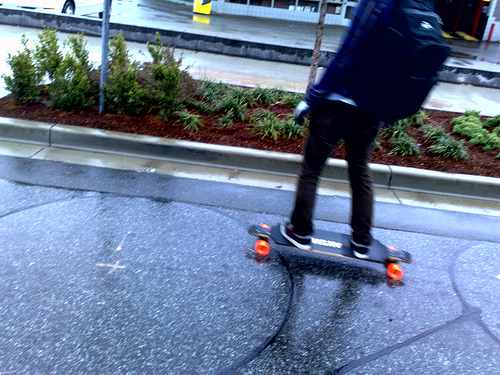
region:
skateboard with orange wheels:
[241, 214, 419, 284]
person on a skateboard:
[286, 0, 453, 272]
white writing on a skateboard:
[310, 234, 347, 252]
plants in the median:
[0, 25, 497, 165]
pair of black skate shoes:
[280, 218, 383, 260]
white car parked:
[1, 2, 121, 29]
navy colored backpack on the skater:
[349, 0, 456, 132]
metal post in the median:
[91, 1, 121, 114]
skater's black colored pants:
[288, 93, 378, 240]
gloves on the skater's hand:
[287, 97, 315, 127]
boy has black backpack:
[345, 3, 432, 134]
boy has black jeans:
[278, 89, 393, 289]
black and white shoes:
[254, 223, 392, 285]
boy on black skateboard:
[254, 223, 386, 290]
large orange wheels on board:
[388, 215, 408, 290]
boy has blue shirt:
[332, 9, 374, 123]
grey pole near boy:
[81, 8, 125, 136]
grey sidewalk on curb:
[11, 116, 293, 204]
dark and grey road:
[50, 196, 241, 370]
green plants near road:
[11, 32, 249, 137]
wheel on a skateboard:
[250, 237, 269, 259]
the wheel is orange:
[385, 263, 403, 283]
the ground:
[58, 274, 277, 357]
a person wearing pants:
[296, 135, 324, 225]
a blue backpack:
[389, 32, 432, 124]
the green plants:
[117, 70, 169, 108]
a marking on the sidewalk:
[88, 255, 138, 277]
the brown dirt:
[132, 111, 169, 136]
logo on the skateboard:
[315, 233, 342, 250]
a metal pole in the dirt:
[100, 38, 110, 115]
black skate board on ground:
[238, 214, 415, 280]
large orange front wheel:
[257, 239, 272, 260]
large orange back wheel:
[381, 257, 406, 283]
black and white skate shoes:
[352, 238, 366, 260]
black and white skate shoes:
[281, 220, 320, 246]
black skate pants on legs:
[286, 93, 389, 250]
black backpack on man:
[312, 8, 452, 119]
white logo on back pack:
[412, 12, 437, 37]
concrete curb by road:
[0, 119, 192, 153]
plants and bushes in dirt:
[115, 68, 211, 119]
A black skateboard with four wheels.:
[246, 221, 415, 281]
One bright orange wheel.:
[383, 258, 405, 283]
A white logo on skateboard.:
[307, 233, 344, 252]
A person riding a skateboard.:
[246, 0, 452, 282]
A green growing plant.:
[173, 105, 203, 136]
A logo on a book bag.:
[415, 18, 437, 33]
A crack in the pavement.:
[23, 139, 53, 164]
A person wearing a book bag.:
[248, 0, 451, 286]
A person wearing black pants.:
[248, 0, 452, 282]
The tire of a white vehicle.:
[60, 1, 76, 16]